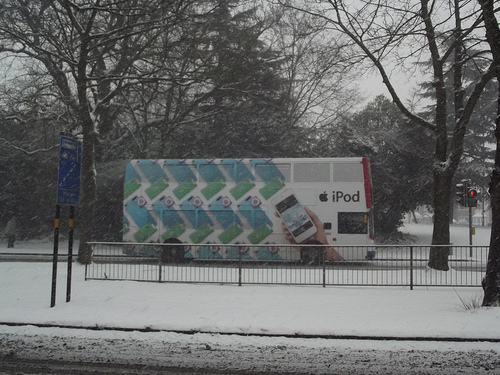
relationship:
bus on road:
[117, 152, 396, 269] [41, 251, 439, 273]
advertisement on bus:
[268, 182, 370, 205] [117, 152, 396, 269]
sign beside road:
[52, 130, 83, 208] [41, 251, 439, 273]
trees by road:
[32, 50, 193, 238] [41, 251, 439, 273]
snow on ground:
[200, 286, 457, 326] [34, 275, 489, 331]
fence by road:
[76, 230, 456, 296] [41, 251, 439, 273]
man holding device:
[4, 211, 15, 259] [5, 224, 8, 233]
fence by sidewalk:
[76, 230, 456, 296] [99, 255, 445, 281]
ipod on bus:
[327, 189, 371, 202] [117, 152, 396, 269]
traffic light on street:
[452, 181, 488, 259] [401, 255, 497, 271]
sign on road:
[52, 130, 83, 208] [41, 251, 439, 273]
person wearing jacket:
[6, 202, 27, 256] [7, 216, 15, 233]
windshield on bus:
[367, 215, 376, 235] [117, 152, 396, 269]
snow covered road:
[200, 286, 457, 326] [41, 251, 439, 273]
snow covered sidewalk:
[200, 286, 457, 326] [99, 255, 445, 281]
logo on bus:
[315, 191, 330, 210] [117, 152, 396, 269]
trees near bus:
[32, 50, 193, 238] [117, 152, 396, 269]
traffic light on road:
[452, 181, 488, 259] [41, 251, 439, 273]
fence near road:
[76, 230, 456, 296] [41, 251, 439, 273]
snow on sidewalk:
[200, 286, 457, 326] [99, 255, 445, 281]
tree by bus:
[398, 54, 484, 266] [117, 152, 396, 269]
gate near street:
[90, 236, 210, 268] [401, 255, 497, 271]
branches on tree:
[363, 35, 475, 123] [398, 54, 484, 266]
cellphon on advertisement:
[275, 195, 323, 245] [268, 182, 370, 205]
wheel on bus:
[160, 238, 186, 263] [117, 152, 396, 269]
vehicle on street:
[122, 180, 380, 255] [401, 255, 497, 271]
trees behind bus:
[32, 50, 193, 238] [117, 152, 396, 269]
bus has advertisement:
[117, 152, 396, 269] [268, 182, 370, 205]